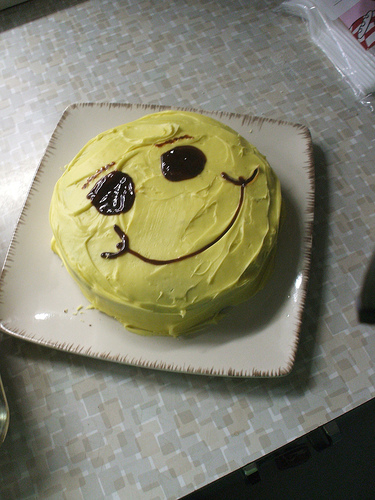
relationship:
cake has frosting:
[43, 106, 290, 342] [48, 107, 284, 340]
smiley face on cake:
[70, 125, 265, 273] [43, 106, 290, 342]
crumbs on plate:
[58, 298, 94, 330] [3, 94, 322, 408]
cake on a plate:
[43, 106, 290, 342] [0, 91, 318, 380]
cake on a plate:
[47, 108, 286, 337] [0, 91, 318, 380]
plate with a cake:
[0, 91, 318, 380] [43, 106, 290, 342]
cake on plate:
[47, 108, 286, 337] [1, 275, 77, 346]